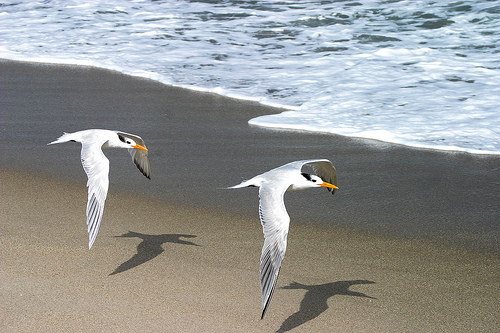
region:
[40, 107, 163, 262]
white bird flying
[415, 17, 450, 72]
white clouds in blue sky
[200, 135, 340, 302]
white bird flying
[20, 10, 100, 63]
wet brown sand on beach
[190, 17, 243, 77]
wet brown sand on beach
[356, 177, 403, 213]
wet brown sand on beach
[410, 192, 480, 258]
wet brown sand on beach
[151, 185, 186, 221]
wet brown sand on beach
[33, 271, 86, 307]
wet brown sand on beach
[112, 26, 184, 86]
wet brown sand on beach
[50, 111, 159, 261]
a seagull flying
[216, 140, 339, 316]
another seagull ahead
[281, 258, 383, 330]
a shadow on the sand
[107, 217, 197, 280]
the shadow is grey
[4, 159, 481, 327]
dry sand under the seagulls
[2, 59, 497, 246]
wet sand under the seagulls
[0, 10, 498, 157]
gentle waves on the beach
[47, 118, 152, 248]
the seagull is white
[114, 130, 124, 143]
a black mark on the seagull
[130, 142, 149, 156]
his beak is orange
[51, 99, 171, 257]
This is a bird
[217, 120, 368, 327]
This is a bird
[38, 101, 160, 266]
bird flying over sand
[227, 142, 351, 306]
bird flying over sand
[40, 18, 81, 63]
wet brown sand on beach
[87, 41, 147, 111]
wet brown sand on beach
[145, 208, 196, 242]
wet brown sand on beach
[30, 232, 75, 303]
wet brown sand on beach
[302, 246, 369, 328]
wet brown sand on beach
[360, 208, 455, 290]
wet brown sand on beach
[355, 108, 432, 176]
wet brown sand on beach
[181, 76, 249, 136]
wet brown sand on beach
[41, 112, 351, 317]
two white sea birds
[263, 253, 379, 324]
a shadow of a bird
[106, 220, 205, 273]
a shadow of a bird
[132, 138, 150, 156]
yellow beak of sea bird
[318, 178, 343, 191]
yellow beak of sea bird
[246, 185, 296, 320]
right wing of sea bird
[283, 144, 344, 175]
left wing of sea bird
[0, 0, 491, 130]
sea water is foamy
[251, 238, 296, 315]
the feathers are gray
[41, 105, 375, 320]
sea birds flying to the right